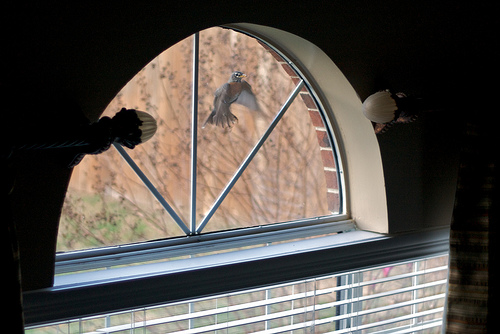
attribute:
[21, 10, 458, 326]
window — long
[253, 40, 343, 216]
brick — red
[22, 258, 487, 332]
blinds — white, mini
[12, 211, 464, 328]
trim — white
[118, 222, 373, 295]
window sill — white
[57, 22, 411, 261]
half circle — window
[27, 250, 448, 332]
window — rectangle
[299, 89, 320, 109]
building brick — red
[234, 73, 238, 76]
eye — black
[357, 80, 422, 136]
light — off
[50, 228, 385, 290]
window sil — white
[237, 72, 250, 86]
beak — orange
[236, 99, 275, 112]
wing — gray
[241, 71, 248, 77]
beak — yellow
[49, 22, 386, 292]
window — arched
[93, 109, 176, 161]
light — white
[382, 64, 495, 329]
curtain — dark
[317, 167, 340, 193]
brick — red